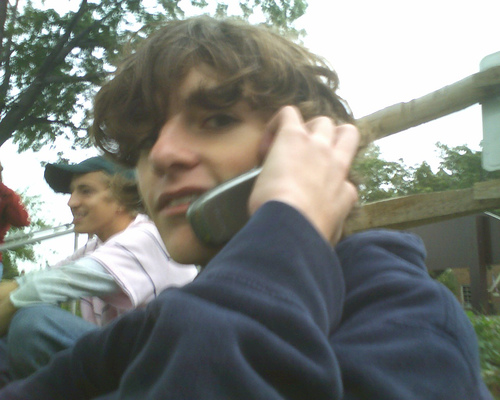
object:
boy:
[2, 10, 494, 397]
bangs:
[91, 38, 261, 168]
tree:
[4, 0, 304, 165]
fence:
[6, 47, 498, 317]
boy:
[0, 155, 199, 397]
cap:
[43, 153, 138, 195]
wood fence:
[310, 68, 495, 146]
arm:
[0, 105, 200, 315]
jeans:
[0, 290, 114, 382]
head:
[89, 19, 361, 264]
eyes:
[193, 107, 239, 136]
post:
[355, 64, 498, 154]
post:
[343, 177, 498, 234]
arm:
[2, 180, 34, 240]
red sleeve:
[2, 177, 36, 245]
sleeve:
[9, 256, 121, 316]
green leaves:
[3, 0, 19, 16]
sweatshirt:
[5, 212, 484, 397]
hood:
[341, 220, 430, 281]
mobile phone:
[185, 164, 262, 247]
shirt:
[0, 152, 210, 383]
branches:
[0, 1, 19, 129]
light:
[349, 25, 429, 62]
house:
[430, 255, 497, 325]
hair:
[81, 10, 371, 241]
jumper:
[0, 13, 491, 394]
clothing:
[1, 175, 33, 255]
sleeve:
[113, 203, 340, 399]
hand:
[266, 99, 364, 248]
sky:
[4, 1, 498, 266]